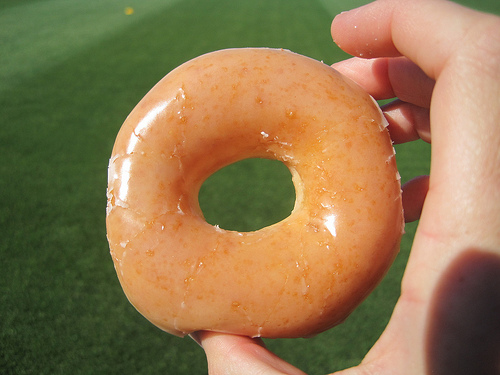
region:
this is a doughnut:
[109, 35, 401, 337]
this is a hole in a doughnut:
[198, 142, 300, 243]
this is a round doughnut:
[104, 30, 398, 339]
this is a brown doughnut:
[102, 18, 417, 335]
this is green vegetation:
[1, 6, 66, 89]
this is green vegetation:
[3, 176, 90, 364]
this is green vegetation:
[214, 10, 311, 45]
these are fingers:
[321, 3, 498, 312]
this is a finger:
[189, 331, 301, 373]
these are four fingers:
[320, 0, 497, 240]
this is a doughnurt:
[116, 45, 387, 327]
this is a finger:
[329, 1, 446, 43]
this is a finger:
[357, 60, 415, 93]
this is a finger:
[394, 107, 422, 133]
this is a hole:
[197, 147, 288, 229]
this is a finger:
[403, 180, 428, 211]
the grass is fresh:
[63, 155, 78, 201]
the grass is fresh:
[40, 172, 58, 248]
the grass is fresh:
[56, 10, 148, 96]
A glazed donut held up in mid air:
[98, 43, 407, 349]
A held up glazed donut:
[98, 43, 423, 351]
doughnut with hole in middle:
[105, 37, 405, 343]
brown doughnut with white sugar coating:
[105, 45, 405, 336]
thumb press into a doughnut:
[166, 312, 303, 369]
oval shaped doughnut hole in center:
[195, 155, 295, 235]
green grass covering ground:
[0, 0, 425, 370]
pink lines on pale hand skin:
[395, 217, 445, 317]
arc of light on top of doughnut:
[110, 90, 175, 210]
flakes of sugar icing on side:
[370, 85, 415, 230]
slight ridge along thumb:
[230, 331, 305, 371]